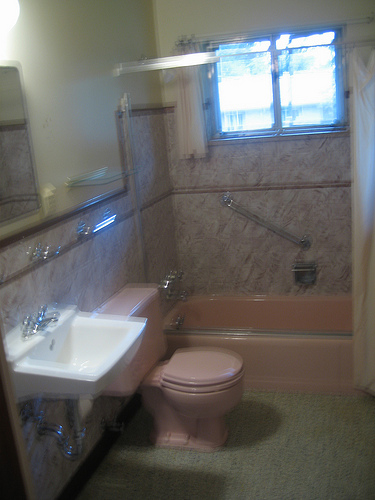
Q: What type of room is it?
A: It is a bathroom.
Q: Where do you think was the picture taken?
A: It was taken at the bathroom.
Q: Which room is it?
A: It is a bathroom.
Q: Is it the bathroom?
A: Yes, it is the bathroom.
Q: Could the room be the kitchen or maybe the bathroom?
A: It is the bathroom.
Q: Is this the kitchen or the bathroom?
A: It is the bathroom.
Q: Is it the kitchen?
A: No, it is the bathroom.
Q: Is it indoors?
A: Yes, it is indoors.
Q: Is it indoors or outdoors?
A: It is indoors.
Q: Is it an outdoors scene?
A: No, it is indoors.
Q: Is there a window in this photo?
A: Yes, there is a window.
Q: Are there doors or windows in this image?
A: Yes, there is a window.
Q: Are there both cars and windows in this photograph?
A: No, there is a window but no cars.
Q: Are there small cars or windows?
A: Yes, there is a small window.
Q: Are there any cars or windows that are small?
A: Yes, the window is small.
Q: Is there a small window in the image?
A: Yes, there is a small window.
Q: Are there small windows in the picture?
A: Yes, there is a small window.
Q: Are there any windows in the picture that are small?
A: Yes, there is a window that is small.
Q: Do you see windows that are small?
A: Yes, there is a window that is small.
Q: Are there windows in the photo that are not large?
A: Yes, there is a small window.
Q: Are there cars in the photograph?
A: No, there are no cars.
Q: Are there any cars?
A: No, there are no cars.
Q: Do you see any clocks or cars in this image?
A: No, there are no cars or clocks.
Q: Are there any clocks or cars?
A: No, there are no cars or clocks.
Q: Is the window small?
A: Yes, the window is small.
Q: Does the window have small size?
A: Yes, the window is small.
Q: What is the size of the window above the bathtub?
A: The window is small.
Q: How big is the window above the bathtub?
A: The window is small.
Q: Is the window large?
A: No, the window is small.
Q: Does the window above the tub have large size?
A: No, the window is small.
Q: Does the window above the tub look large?
A: No, the window is small.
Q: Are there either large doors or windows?
A: No, there is a window but it is small.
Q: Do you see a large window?
A: No, there is a window but it is small.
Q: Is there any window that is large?
A: No, there is a window but it is small.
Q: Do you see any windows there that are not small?
A: No, there is a window but it is small.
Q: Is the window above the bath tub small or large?
A: The window is small.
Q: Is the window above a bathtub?
A: Yes, the window is above a bathtub.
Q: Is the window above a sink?
A: No, the window is above a bathtub.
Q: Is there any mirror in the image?
A: Yes, there is a mirror.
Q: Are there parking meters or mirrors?
A: Yes, there is a mirror.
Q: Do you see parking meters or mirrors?
A: Yes, there is a mirror.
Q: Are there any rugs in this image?
A: No, there are no rugs.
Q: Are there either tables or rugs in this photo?
A: No, there are no rugs or tables.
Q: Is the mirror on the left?
A: Yes, the mirror is on the left of the image.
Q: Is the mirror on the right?
A: No, the mirror is on the left of the image.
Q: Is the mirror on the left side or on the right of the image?
A: The mirror is on the left of the image.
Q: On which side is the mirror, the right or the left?
A: The mirror is on the left of the image.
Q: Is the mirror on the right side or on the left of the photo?
A: The mirror is on the left of the image.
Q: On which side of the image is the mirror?
A: The mirror is on the left of the image.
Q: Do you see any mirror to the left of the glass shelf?
A: Yes, there is a mirror to the left of the shelf.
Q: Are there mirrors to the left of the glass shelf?
A: Yes, there is a mirror to the left of the shelf.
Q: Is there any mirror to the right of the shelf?
A: No, the mirror is to the left of the shelf.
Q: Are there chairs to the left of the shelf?
A: No, there is a mirror to the left of the shelf.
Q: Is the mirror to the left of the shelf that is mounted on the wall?
A: Yes, the mirror is to the left of the shelf.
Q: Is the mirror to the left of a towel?
A: No, the mirror is to the left of the shelf.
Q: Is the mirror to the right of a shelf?
A: No, the mirror is to the left of a shelf.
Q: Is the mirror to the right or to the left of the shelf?
A: The mirror is to the left of the shelf.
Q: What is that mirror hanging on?
A: The mirror is hanging on the wall.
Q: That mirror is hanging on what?
A: The mirror is hanging on the wall.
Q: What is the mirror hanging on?
A: The mirror is hanging on the wall.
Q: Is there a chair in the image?
A: No, there are no chairs.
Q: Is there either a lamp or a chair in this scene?
A: No, there are no chairs or lamps.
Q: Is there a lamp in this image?
A: No, there are no lamps.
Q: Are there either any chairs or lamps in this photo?
A: No, there are no lamps or chairs.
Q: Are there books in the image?
A: No, there are no books.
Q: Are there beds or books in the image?
A: No, there are no books or beds.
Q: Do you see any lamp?
A: No, there are no lamps.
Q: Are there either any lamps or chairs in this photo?
A: No, there are no lamps or chairs.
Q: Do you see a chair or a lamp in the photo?
A: No, there are no lamps or chairs.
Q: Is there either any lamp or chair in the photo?
A: No, there are no lamps or chairs.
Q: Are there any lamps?
A: No, there are no lamps.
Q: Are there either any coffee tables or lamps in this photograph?
A: No, there are no lamps or coffee tables.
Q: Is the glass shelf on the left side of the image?
A: Yes, the shelf is on the left of the image.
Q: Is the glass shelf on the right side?
A: No, the shelf is on the left of the image.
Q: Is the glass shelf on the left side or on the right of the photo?
A: The shelf is on the left of the image.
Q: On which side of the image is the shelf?
A: The shelf is on the left of the image.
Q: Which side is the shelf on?
A: The shelf is on the left of the image.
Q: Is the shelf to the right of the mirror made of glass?
A: Yes, the shelf is made of glass.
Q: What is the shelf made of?
A: The shelf is made of glass.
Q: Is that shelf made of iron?
A: No, the shelf is made of glass.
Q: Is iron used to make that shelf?
A: No, the shelf is made of glass.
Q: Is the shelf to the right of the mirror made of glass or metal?
A: The shelf is made of glass.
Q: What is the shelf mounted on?
A: The shelf is mounted on the wall.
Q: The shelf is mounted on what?
A: The shelf is mounted on the wall.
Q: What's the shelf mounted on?
A: The shelf is mounted on the wall.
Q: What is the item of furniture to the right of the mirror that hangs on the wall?
A: The piece of furniture is a shelf.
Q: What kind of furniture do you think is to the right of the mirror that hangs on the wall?
A: The piece of furniture is a shelf.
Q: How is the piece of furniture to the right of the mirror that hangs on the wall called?
A: The piece of furniture is a shelf.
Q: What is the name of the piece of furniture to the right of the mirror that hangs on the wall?
A: The piece of furniture is a shelf.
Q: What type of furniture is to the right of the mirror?
A: The piece of furniture is a shelf.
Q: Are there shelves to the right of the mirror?
A: Yes, there is a shelf to the right of the mirror.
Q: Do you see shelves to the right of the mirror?
A: Yes, there is a shelf to the right of the mirror.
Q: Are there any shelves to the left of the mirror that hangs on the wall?
A: No, the shelf is to the right of the mirror.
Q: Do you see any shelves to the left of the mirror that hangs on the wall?
A: No, the shelf is to the right of the mirror.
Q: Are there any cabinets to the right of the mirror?
A: No, there is a shelf to the right of the mirror.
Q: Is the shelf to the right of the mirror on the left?
A: Yes, the shelf is to the right of the mirror.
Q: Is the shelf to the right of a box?
A: No, the shelf is to the right of the mirror.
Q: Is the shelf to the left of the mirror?
A: No, the shelf is to the right of the mirror.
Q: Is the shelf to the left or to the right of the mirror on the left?
A: The shelf is to the right of the mirror.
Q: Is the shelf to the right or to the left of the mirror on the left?
A: The shelf is to the right of the mirror.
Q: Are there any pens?
A: No, there are no pens.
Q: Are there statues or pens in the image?
A: No, there are no pens or statues.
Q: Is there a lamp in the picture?
A: No, there are no lamps.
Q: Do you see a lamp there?
A: No, there are no lamps.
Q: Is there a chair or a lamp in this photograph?
A: No, there are no lamps or chairs.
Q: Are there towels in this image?
A: No, there are no towels.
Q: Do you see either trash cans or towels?
A: No, there are no towels or trash cans.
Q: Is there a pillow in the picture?
A: No, there are no pillows.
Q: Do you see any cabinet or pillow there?
A: No, there are no pillows or cabinets.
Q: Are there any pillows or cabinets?
A: No, there are no pillows or cabinets.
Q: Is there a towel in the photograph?
A: No, there are no towels.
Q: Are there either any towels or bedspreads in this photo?
A: No, there are no towels or bedspreads.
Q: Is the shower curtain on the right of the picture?
A: Yes, the shower curtain is on the right of the image.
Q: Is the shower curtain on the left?
A: No, the shower curtain is on the right of the image.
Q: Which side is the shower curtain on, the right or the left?
A: The shower curtain is on the right of the image.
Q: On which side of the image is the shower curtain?
A: The shower curtain is on the right of the image.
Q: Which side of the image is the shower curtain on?
A: The shower curtain is on the right of the image.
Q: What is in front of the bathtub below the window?
A: The shower curtain is in front of the bathtub.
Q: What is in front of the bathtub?
A: The shower curtain is in front of the bathtub.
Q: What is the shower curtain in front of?
A: The shower curtain is in front of the bathtub.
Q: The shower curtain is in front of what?
A: The shower curtain is in front of the bathtub.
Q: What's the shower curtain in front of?
A: The shower curtain is in front of the bathtub.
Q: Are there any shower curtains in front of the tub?
A: Yes, there is a shower curtain in front of the tub.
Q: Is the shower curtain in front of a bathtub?
A: Yes, the shower curtain is in front of a bathtub.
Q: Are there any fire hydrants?
A: No, there are no fire hydrants.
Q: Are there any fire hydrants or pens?
A: No, there are no fire hydrants or pens.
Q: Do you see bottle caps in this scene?
A: No, there are no bottle caps.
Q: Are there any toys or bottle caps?
A: No, there are no bottle caps or toys.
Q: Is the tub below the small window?
A: Yes, the tub is below the window.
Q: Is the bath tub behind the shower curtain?
A: Yes, the bath tub is behind the shower curtain.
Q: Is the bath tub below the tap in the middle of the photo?
A: Yes, the bath tub is below the tap.